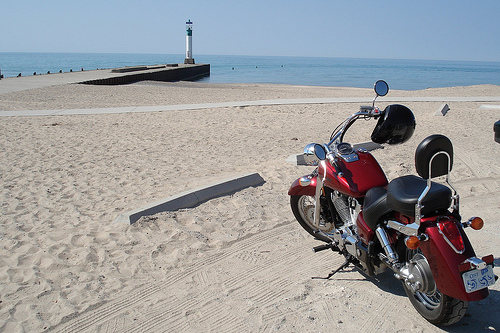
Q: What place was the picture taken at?
A: It was taken at the beach.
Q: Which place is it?
A: It is a beach.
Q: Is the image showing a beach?
A: Yes, it is showing a beach.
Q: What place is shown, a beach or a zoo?
A: It is a beach.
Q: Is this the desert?
A: No, it is the beach.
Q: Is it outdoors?
A: Yes, it is outdoors.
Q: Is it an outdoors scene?
A: Yes, it is outdoors.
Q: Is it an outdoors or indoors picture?
A: It is outdoors.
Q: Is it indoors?
A: No, it is outdoors.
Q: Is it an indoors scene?
A: No, it is outdoors.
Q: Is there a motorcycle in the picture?
A: Yes, there is a motorcycle.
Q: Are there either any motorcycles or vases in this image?
A: Yes, there is a motorcycle.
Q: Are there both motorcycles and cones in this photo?
A: No, there is a motorcycle but no cones.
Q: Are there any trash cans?
A: No, there are no trash cans.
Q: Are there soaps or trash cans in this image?
A: No, there are no trash cans or soaps.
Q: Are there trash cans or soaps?
A: No, there are no trash cans or soaps.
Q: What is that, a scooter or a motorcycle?
A: That is a motorcycle.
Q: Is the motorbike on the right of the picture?
A: Yes, the motorbike is on the right of the image.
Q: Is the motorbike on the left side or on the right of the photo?
A: The motorbike is on the right of the image.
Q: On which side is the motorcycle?
A: The motorcycle is on the right of the image.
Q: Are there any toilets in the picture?
A: No, there are no toilets.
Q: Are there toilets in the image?
A: No, there are no toilets.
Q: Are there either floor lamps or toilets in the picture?
A: No, there are no toilets or floor lamps.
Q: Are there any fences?
A: No, there are no fences.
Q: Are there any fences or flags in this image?
A: No, there are no fences or flags.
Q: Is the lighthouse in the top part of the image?
A: Yes, the lighthouse is in the top of the image.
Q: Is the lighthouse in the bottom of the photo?
A: No, the lighthouse is in the top of the image.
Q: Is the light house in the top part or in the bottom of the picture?
A: The light house is in the top of the image.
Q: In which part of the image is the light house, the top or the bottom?
A: The light house is in the top of the image.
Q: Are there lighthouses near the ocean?
A: Yes, there is a lighthouse near the ocean.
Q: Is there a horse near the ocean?
A: No, there is a lighthouse near the ocean.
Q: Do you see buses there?
A: No, there are no buses.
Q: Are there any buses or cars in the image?
A: No, there are no buses or cars.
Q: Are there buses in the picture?
A: No, there are no buses.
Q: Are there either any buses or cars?
A: No, there are no buses or cars.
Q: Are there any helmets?
A: Yes, there is a helmet.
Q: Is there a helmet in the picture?
A: Yes, there is a helmet.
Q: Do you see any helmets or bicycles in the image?
A: Yes, there is a helmet.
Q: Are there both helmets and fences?
A: No, there is a helmet but no fences.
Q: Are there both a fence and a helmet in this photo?
A: No, there is a helmet but no fences.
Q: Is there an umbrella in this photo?
A: No, there are no umbrellas.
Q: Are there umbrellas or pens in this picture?
A: No, there are no umbrellas or pens.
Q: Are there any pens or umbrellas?
A: No, there are no umbrellas or pens.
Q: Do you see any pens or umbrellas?
A: No, there are no umbrellas or pens.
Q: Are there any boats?
A: No, there are no boats.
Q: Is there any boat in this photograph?
A: No, there are no boats.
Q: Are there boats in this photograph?
A: No, there are no boats.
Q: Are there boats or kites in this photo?
A: No, there are no boats or kites.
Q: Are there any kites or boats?
A: No, there are no boats or kites.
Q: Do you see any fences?
A: No, there are no fences.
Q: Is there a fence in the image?
A: No, there are no fences.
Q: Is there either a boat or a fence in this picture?
A: No, there are no fences or boats.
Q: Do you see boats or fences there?
A: No, there are no fences or boats.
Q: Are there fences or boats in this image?
A: No, there are no fences or boats.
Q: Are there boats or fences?
A: No, there are no fences or boats.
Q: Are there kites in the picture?
A: No, there are no kites.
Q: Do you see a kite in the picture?
A: No, there are no kites.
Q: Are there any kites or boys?
A: No, there are no kites or boys.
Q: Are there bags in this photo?
A: No, there are no bags.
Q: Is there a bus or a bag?
A: No, there are no bags or buses.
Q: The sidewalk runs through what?
A: The sidewalk runs through the beach.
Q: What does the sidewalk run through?
A: The sidewalk runs through the beach.